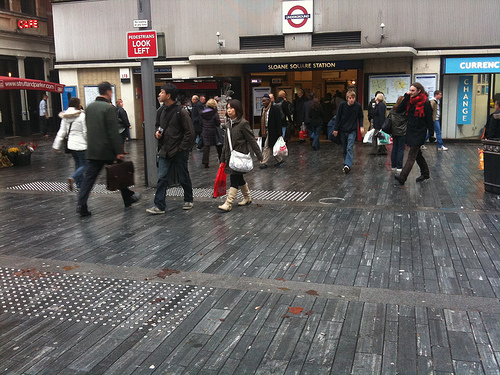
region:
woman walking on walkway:
[209, 97, 269, 217]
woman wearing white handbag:
[221, 120, 256, 178]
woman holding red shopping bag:
[208, 158, 230, 201]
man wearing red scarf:
[403, 89, 432, 120]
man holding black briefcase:
[103, 155, 136, 195]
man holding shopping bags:
[270, 133, 288, 165]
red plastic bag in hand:
[205, 159, 231, 201]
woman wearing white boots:
[220, 180, 256, 211]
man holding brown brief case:
[93, 155, 155, 194]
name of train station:
[248, 57, 344, 72]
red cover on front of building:
[2, 71, 68, 100]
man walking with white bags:
[245, 88, 296, 172]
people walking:
[31, 80, 451, 222]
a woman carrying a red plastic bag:
[206, 95, 267, 212]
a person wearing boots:
[208, 96, 268, 213]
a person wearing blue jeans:
[331, 85, 368, 176]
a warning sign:
[123, 30, 159, 60]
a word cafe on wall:
[11, 16, 41, 32]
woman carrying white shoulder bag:
[203, 95, 271, 215]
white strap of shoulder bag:
[224, 128, 234, 150]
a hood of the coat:
[198, 105, 216, 122]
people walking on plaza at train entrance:
[10, 5, 482, 362]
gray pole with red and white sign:
[127, 3, 162, 191]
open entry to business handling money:
[437, 50, 497, 142]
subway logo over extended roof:
[188, 2, 415, 67]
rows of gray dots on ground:
[7, 257, 214, 340]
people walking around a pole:
[69, 78, 266, 220]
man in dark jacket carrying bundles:
[250, 92, 287, 169]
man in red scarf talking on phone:
[394, 79, 435, 189]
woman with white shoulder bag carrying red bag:
[212, 97, 267, 217]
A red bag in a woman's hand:
[207, 162, 229, 204]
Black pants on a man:
[155, 153, 190, 206]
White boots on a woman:
[214, 188, 252, 208]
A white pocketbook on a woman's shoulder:
[222, 130, 253, 170]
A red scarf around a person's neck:
[404, 90, 426, 115]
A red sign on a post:
[126, 30, 157, 58]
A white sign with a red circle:
[281, 0, 313, 32]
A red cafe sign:
[17, 18, 37, 29]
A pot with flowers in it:
[2, 143, 36, 163]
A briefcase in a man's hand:
[104, 158, 137, 191]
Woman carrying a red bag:
[210, 93, 270, 199]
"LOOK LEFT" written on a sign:
[125, 35, 151, 55]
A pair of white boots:
[211, 176, 252, 211]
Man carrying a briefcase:
[80, 76, 140, 192]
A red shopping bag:
[208, 161, 230, 198]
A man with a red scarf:
[397, 80, 439, 185]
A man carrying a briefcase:
[74, 77, 141, 212]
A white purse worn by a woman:
[221, 122, 258, 174]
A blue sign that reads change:
[455, 73, 472, 125]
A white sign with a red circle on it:
[279, 1, 314, 33]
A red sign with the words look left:
[125, 29, 159, 58]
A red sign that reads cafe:
[14, 20, 41, 31]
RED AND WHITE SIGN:
[105, 14, 172, 74]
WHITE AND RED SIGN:
[270, 1, 327, 46]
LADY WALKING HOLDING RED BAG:
[198, 92, 272, 227]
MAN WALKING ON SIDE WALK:
[388, 67, 447, 207]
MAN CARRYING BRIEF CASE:
[89, 132, 146, 220]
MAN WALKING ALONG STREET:
[134, 80, 213, 233]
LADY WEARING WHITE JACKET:
[26, 91, 97, 173]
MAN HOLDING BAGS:
[251, 94, 304, 184]